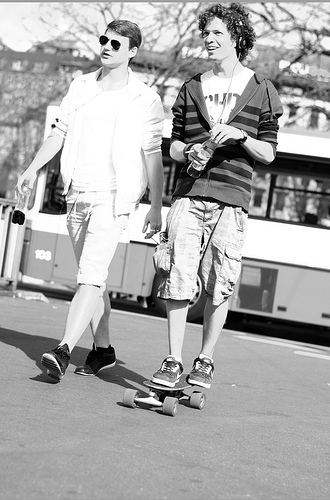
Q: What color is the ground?
A: Grey.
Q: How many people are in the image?
A: Two.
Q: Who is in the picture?
A: Two males.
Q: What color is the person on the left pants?
A: White.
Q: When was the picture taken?
A: While the people were moving.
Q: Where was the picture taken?
A: Pavement.